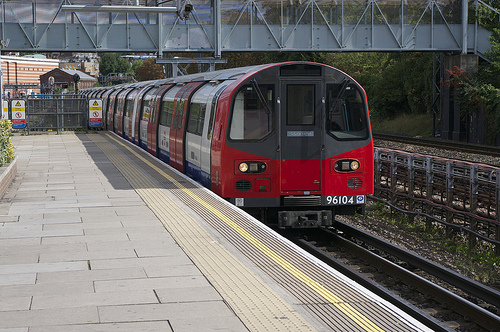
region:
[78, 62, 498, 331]
Train moving on the tracks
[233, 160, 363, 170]
Train headlights on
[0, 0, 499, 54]
Walk way over train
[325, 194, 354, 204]
Train identification number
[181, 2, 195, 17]
Observation camera over tracks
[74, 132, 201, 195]
Shadow of train on walkway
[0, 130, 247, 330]
Paved concrete walkway by tracks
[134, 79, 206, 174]
Closed train doors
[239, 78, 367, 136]
Windshield wipers on train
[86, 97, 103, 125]
Signage for train passengers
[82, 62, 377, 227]
red and white train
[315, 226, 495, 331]
metal and wood train tracks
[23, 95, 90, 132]
wood and metal fence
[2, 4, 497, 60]
grey metal walking bridge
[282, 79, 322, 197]
black and red door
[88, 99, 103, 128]
sign hanging on fence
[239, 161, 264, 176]
head light on train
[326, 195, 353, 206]
white numbers on train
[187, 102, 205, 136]
window on train car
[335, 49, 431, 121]
tree with green leaves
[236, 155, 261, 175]
Headlight for red train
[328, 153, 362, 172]
Headlight for red train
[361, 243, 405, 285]
Part of train tracks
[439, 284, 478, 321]
Part of train tracks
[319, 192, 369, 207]
Number for red train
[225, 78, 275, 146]
Window for red train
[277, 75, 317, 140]
Window for red train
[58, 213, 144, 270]
concrete area near red train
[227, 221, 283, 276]
Yellow caution line near train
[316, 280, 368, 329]
Yellow caution line near train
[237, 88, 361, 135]
window of a train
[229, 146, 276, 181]
light of a train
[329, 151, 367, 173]
light of a train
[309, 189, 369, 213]
number of a train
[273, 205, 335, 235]
mount of a train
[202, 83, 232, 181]
door of a train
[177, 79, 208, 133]
window of a train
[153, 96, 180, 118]
window of a train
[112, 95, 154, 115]
window of a train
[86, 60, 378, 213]
train is red and white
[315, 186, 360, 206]
white numbers on train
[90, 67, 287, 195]
reflection on the train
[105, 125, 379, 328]
yellow line on the platform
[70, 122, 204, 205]
shadow of train on ground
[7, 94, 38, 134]
sign is red white yellow and blue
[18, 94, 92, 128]
metal fence between signs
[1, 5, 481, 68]
metal structure above train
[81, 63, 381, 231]
train is not moving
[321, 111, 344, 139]
driver seat is empty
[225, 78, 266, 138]
a window on a train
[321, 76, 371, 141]
a window on a train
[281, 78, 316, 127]
a window on a train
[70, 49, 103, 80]
a building in a city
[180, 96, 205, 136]
a window on a train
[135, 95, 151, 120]
a window on a train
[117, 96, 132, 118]
a window on a train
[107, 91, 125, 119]
a window on a train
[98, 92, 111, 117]
a window on a train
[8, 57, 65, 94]
a building in a city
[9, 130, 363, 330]
platform next to the train